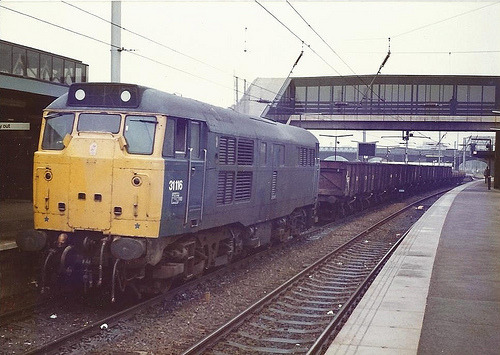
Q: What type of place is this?
A: It is a station.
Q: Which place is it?
A: It is a station.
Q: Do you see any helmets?
A: No, there are no helmets.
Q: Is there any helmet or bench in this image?
A: No, there are no helmets or benches.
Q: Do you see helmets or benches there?
A: No, there are no helmets or benches.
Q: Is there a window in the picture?
A: Yes, there are windows.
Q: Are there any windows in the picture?
A: Yes, there are windows.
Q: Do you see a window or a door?
A: Yes, there are windows.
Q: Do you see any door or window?
A: Yes, there are windows.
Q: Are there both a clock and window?
A: No, there are windows but no clocks.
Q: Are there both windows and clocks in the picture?
A: No, there are windows but no clocks.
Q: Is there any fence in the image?
A: No, there are no fences.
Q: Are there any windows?
A: Yes, there are windows.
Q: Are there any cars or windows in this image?
A: Yes, there are windows.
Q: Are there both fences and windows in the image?
A: No, there are windows but no fences.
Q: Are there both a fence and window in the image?
A: No, there are windows but no fences.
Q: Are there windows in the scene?
A: Yes, there are windows.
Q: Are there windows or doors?
A: Yes, there are windows.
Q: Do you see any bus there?
A: No, there are no buses.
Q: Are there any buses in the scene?
A: No, there are no buses.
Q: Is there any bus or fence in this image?
A: No, there are no buses or fences.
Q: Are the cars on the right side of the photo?
A: Yes, the cars are on the right of the image.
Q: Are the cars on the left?
A: No, the cars are on the right of the image.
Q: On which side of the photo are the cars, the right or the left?
A: The cars are on the right of the image.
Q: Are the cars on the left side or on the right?
A: The cars are on the right of the image.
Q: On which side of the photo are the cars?
A: The cars are on the right of the image.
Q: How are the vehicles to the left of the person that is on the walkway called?
A: The vehicles are cars.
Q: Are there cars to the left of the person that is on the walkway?
A: Yes, there are cars to the left of the person.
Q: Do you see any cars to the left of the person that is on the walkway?
A: Yes, there are cars to the left of the person.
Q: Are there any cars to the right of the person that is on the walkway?
A: No, the cars are to the left of the person.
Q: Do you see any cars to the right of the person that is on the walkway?
A: No, the cars are to the left of the person.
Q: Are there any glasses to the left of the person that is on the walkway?
A: No, there are cars to the left of the person.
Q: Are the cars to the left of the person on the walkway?
A: Yes, the cars are to the left of the person.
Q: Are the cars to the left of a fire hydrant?
A: No, the cars are to the left of the person.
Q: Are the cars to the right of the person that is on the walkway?
A: No, the cars are to the left of the person.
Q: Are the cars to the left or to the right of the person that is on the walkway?
A: The cars are to the left of the person.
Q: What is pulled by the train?
A: The cars are pulled by the train.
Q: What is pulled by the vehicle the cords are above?
A: The cars are pulled by the train.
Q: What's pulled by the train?
A: The cars are pulled by the train.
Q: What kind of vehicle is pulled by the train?
A: The vehicles are cars.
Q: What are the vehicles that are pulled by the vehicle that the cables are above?
A: The vehicles are cars.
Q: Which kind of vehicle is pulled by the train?
A: The vehicles are cars.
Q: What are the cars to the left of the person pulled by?
A: The cars are pulled by the train.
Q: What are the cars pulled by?
A: The cars are pulled by the train.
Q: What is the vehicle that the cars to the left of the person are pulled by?
A: The vehicle is a train.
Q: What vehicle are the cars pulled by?
A: The cars are pulled by the train.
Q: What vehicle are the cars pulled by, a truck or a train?
A: The cars are pulled by a train.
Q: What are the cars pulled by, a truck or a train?
A: The cars are pulled by a train.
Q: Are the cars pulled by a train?
A: Yes, the cars are pulled by a train.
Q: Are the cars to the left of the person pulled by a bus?
A: No, the cars are pulled by a train.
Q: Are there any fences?
A: No, there are no fences.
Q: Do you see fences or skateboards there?
A: No, there are no fences or skateboards.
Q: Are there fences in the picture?
A: No, there are no fences.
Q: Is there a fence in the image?
A: No, there are no fences.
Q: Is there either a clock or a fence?
A: No, there are no fences or clocks.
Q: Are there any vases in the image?
A: No, there are no vases.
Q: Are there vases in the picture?
A: No, there are no vases.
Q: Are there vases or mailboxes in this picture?
A: No, there are no vases or mailboxes.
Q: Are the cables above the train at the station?
A: Yes, the cables are above the train.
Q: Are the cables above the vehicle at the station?
A: Yes, the cables are above the train.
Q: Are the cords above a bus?
A: No, the cords are above the train.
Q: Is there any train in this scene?
A: Yes, there is a train.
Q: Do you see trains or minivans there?
A: Yes, there is a train.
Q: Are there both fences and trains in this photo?
A: No, there is a train but no fences.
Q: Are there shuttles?
A: No, there are no shuttles.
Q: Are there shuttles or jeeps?
A: No, there are no shuttles or jeeps.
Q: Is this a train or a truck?
A: This is a train.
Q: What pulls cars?
A: The train pulls cars.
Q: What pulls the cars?
A: The train pulls cars.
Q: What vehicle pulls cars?
A: The vehicle is a train.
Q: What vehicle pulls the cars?
A: The vehicle is a train.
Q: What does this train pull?
A: The train pulls cars.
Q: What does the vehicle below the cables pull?
A: The train pulls cars.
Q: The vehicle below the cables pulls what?
A: The train pulls cars.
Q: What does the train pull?
A: The train pulls cars.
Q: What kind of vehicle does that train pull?
A: The train pulls cars.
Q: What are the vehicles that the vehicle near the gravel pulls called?
A: The vehicles are cars.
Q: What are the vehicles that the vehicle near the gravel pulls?
A: The vehicles are cars.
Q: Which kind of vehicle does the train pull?
A: The train pulls cars.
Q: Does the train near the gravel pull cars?
A: Yes, the train pulls cars.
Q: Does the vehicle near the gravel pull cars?
A: Yes, the train pulls cars.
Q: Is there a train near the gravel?
A: Yes, there is a train near the gravel.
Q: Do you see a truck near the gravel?
A: No, there is a train near the gravel.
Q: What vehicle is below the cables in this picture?
A: The vehicle is a train.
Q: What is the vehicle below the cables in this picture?
A: The vehicle is a train.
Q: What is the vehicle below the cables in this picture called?
A: The vehicle is a train.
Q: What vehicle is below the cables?
A: The vehicle is a train.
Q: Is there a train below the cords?
A: Yes, there is a train below the cords.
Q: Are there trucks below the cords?
A: No, there is a train below the cords.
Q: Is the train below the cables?
A: Yes, the train is below the cables.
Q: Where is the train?
A: The train is at the station.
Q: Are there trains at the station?
A: Yes, there is a train at the station.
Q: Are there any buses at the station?
A: No, there is a train at the station.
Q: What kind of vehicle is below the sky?
A: The vehicle is a train.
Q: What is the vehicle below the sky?
A: The vehicle is a train.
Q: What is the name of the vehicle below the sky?
A: The vehicle is a train.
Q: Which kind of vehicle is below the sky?
A: The vehicle is a train.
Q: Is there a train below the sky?
A: Yes, there is a train below the sky.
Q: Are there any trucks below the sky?
A: No, there is a train below the sky.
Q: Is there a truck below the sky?
A: No, there is a train below the sky.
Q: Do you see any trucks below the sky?
A: No, there is a train below the sky.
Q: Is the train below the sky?
A: Yes, the train is below the sky.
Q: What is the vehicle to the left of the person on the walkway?
A: The vehicle is a train.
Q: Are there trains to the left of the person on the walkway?
A: Yes, there is a train to the left of the person.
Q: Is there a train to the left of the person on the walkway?
A: Yes, there is a train to the left of the person.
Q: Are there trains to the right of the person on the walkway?
A: No, the train is to the left of the person.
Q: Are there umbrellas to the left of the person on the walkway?
A: No, there is a train to the left of the person.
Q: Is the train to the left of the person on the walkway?
A: Yes, the train is to the left of the person.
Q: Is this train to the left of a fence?
A: No, the train is to the left of the person.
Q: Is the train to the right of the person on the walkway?
A: No, the train is to the left of the person.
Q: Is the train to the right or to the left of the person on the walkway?
A: The train is to the left of the person.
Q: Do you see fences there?
A: No, there are no fences.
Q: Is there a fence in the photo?
A: No, there are no fences.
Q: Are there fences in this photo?
A: No, there are no fences.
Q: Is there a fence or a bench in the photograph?
A: No, there are no fences or benches.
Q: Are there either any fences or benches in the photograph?
A: No, there are no fences or benches.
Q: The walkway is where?
A: The walkway is at the station.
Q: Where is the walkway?
A: The walkway is at the station.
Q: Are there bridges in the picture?
A: Yes, there is a bridge.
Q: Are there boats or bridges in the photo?
A: Yes, there is a bridge.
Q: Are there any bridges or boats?
A: Yes, there is a bridge.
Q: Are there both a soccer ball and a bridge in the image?
A: No, there is a bridge but no soccer balls.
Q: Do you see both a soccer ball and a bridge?
A: No, there is a bridge but no soccer balls.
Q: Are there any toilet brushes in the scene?
A: No, there are no toilet brushes.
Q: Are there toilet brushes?
A: No, there are no toilet brushes.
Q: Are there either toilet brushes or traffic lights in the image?
A: No, there are no toilet brushes or traffic lights.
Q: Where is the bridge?
A: The bridge is at the station.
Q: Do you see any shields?
A: No, there are no shields.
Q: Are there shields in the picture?
A: No, there are no shields.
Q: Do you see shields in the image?
A: No, there are no shields.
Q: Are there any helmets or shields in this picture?
A: No, there are no shields or helmets.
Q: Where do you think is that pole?
A: The pole is at the station.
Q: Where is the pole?
A: The pole is at the station.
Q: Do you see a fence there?
A: No, there are no fences.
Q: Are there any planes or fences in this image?
A: No, there are no fences or planes.